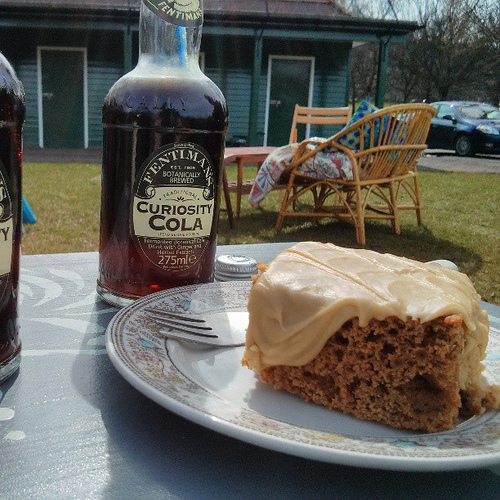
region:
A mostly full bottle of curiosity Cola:
[97, 2, 229, 313]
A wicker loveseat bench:
[275, 103, 442, 237]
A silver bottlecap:
[208, 244, 258, 286]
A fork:
[142, 254, 466, 350]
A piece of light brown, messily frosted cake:
[240, 224, 498, 451]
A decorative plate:
[83, 272, 498, 497]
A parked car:
[392, 82, 499, 151]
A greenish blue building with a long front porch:
[1, 2, 423, 169]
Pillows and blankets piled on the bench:
[250, 98, 428, 211]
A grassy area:
[2, 152, 499, 292]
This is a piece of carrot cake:
[333, 260, 415, 380]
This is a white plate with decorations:
[190, 387, 247, 431]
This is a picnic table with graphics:
[60, 388, 86, 448]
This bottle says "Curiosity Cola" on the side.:
[138, 190, 215, 244]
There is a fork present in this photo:
[166, 293, 237, 353]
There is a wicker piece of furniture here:
[355, 108, 441, 200]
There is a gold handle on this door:
[262, 86, 280, 120]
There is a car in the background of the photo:
[436, 87, 494, 162]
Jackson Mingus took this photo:
[92, 30, 399, 410]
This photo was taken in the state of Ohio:
[131, 97, 387, 437]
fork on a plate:
[146, 285, 228, 359]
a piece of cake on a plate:
[251, 268, 333, 456]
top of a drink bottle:
[212, 224, 262, 287]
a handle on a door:
[40, 84, 59, 106]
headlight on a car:
[471, 115, 498, 140]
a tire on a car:
[449, 123, 478, 163]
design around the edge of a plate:
[121, 320, 168, 393]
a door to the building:
[26, 37, 115, 164]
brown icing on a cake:
[253, 261, 312, 324]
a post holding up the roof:
[243, 13, 270, 136]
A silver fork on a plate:
[144, 256, 461, 349]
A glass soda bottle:
[93, 0, 231, 313]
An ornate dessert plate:
[102, 277, 499, 472]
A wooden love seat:
[274, 102, 440, 247]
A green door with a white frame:
[34, 42, 91, 151]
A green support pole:
[245, 30, 264, 146]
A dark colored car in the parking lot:
[425, 92, 498, 156]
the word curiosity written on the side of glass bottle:
[132, 198, 216, 216]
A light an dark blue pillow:
[323, 98, 404, 157]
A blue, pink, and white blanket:
[245, 140, 378, 214]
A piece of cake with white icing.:
[232, 220, 499, 434]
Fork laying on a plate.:
[142, 281, 352, 411]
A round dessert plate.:
[99, 254, 495, 478]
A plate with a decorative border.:
[103, 253, 498, 478]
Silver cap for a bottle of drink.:
[211, 238, 257, 288]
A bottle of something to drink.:
[90, 4, 231, 311]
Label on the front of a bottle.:
[119, 129, 221, 282]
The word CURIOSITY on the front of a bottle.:
[134, 197, 217, 216]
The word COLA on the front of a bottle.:
[138, 210, 210, 235]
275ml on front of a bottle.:
[152, 250, 193, 267]